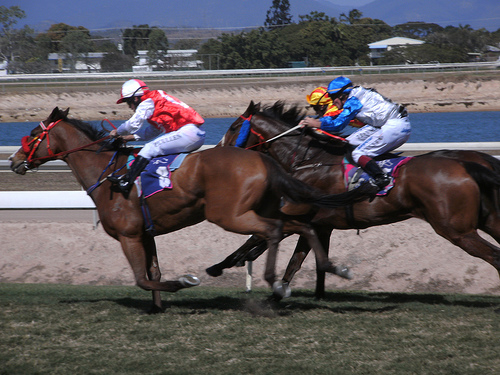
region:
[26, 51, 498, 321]
three men are raising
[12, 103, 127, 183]
the horse has red briddles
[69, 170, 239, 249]
its brown in colour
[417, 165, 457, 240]
the horse is black in colour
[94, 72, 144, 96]
the helmet is red and white in colour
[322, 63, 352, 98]
the helmet is blue in colour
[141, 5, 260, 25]
the sky is blue in colour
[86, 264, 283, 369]
the grass is green in colour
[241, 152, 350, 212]
the tail is black in colour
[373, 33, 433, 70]
the horse is white in colour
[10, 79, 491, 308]
three people riding horses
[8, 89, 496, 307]
three racing horses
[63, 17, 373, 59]
power lines above the trees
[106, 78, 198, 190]
jockey wearing red and white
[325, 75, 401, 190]
jockey wearing blue and white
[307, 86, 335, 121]
jockey wearing red and gold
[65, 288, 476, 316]
shadows being cast on the ground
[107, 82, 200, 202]
jockey wearing black boots and a red and white hat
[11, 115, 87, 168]
red horse halter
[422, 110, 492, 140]
water behind the horses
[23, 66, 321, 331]
jockey on a horse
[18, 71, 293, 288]
jockey with red shirt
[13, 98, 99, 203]
horses head with red bridle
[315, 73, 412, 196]
jockey in blue and white colors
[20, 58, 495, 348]
three jockies racing horses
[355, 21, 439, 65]
roof of house and tree tops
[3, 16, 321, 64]
utility wires and treetops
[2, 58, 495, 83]
guard rail along road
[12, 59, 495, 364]
horses racing in grass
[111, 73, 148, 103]
red and white cap with visor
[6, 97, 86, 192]
a brown horse head.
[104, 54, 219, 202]
a jockey riding a horse.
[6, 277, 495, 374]
grass on a race track.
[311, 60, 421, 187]
a jockey riding a horse.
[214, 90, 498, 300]
a brown horse racing.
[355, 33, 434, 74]
a tent in a field.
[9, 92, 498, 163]
a wall near a race track.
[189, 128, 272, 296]
the back leg of a horse.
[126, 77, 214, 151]
a rider in an orange shirt.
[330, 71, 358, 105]
a man in a blue hat.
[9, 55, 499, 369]
horses racing on grass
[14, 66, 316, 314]
jockey riding on horse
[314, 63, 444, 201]
jockey wearing blue and white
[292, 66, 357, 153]
jockey wearing yellow and red colors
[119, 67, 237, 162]
jockey wearing red and white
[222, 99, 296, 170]
blue and red halter on horse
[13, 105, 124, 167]
red halter and reins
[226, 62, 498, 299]
water and sand near horse racing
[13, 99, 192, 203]
brown horse with black mane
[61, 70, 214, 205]
jockey wearing black knee-length riding boots